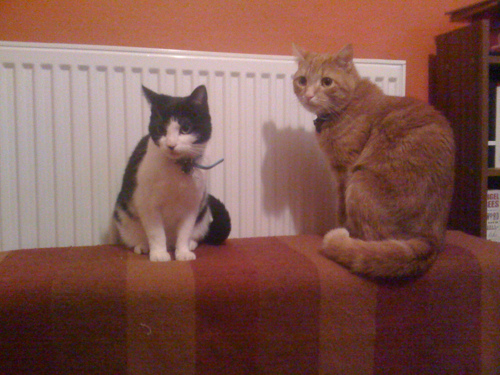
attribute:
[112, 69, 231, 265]
cat — gray, white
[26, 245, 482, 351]
bench — orange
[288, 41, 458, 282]
orange cat — sitting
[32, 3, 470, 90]
wall — orange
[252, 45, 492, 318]
cat — orange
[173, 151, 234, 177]
collar — black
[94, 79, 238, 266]
cat — white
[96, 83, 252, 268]
cat — black, white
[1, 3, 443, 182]
wall — orange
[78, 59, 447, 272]
cat — white, black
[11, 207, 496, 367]
bench — light, dark, orange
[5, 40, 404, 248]
back rest — white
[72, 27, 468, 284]
cats — sitting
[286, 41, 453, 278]
cat — sitting, orange, striped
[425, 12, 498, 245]
book shelf — wooden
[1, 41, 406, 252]
panel — white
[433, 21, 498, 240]
bookcase — wood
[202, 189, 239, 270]
tail — white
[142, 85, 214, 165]
head — white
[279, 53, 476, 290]
cat — brown, tan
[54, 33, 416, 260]
panel — white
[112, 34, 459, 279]
cats — sitting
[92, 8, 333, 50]
wall — orange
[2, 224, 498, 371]
ottoman — striped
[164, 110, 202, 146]
markings — black, white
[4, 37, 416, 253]
back — white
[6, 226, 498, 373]
bench — orange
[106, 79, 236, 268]
cat — black, white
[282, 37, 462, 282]
cat — tan, brown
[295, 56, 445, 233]
cat — tan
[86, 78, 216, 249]
cat — black